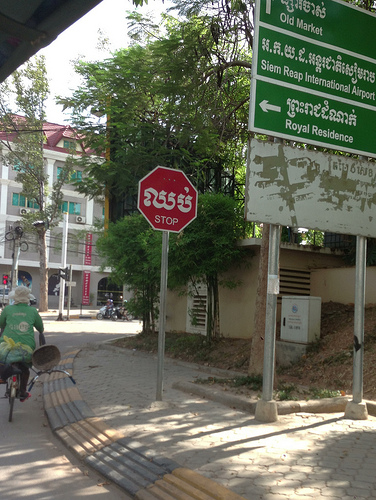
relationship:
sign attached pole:
[135, 162, 200, 234] [60, 210, 70, 313]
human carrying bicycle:
[0, 285, 46, 387] [0, 364, 26, 422]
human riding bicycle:
[0, 285, 46, 387] [0, 343, 44, 423]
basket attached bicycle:
[18, 308, 78, 403] [7, 319, 92, 445]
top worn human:
[0, 306, 49, 362] [2, 283, 55, 417]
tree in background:
[1, 65, 65, 314] [5, 108, 136, 319]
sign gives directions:
[245, 75, 375, 162] [253, 90, 288, 128]